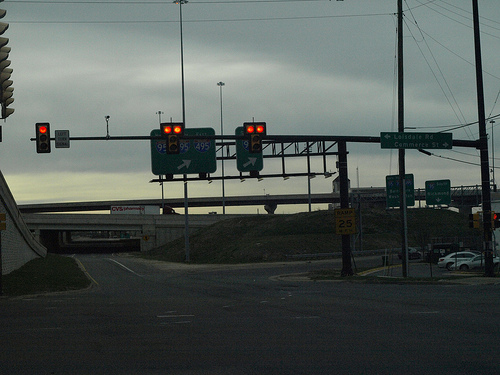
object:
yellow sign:
[335, 207, 359, 238]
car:
[439, 249, 485, 273]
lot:
[373, 239, 499, 287]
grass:
[0, 252, 92, 296]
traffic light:
[159, 121, 186, 155]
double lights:
[160, 121, 187, 135]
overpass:
[18, 191, 343, 223]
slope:
[149, 213, 337, 263]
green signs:
[151, 130, 218, 176]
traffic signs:
[384, 174, 453, 209]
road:
[0, 210, 500, 375]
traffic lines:
[106, 252, 153, 283]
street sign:
[380, 131, 455, 151]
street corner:
[309, 249, 406, 301]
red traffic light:
[244, 121, 269, 135]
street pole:
[26, 134, 480, 150]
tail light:
[440, 257, 446, 264]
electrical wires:
[6, 24, 403, 36]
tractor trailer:
[110, 201, 183, 217]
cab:
[163, 204, 177, 218]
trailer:
[110, 202, 161, 216]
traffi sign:
[236, 127, 266, 172]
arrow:
[243, 157, 258, 168]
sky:
[8, 0, 500, 219]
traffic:
[1, 176, 499, 374]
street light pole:
[176, 0, 191, 266]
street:
[0, 234, 500, 375]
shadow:
[71, 236, 138, 256]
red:
[244, 121, 269, 132]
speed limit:
[339, 215, 353, 231]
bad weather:
[2, 1, 500, 374]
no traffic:
[1, 215, 400, 372]